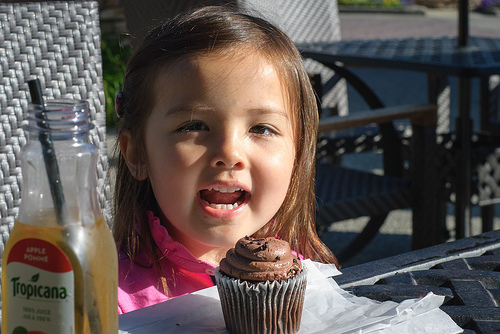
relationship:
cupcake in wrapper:
[214, 234, 308, 333] [215, 272, 306, 332]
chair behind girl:
[0, 0, 115, 241] [108, 7, 336, 311]